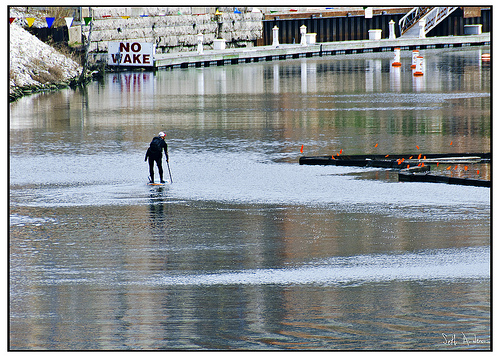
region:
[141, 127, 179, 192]
person paddle boarding on water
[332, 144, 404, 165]
small orange flags on divider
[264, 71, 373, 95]
reflection on calm water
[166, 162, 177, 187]
paddle board oar in water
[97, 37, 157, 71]
sign warning not to make wake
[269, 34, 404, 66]
dock on water's edge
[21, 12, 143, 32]
multi colored triangle flags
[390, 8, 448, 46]
ramp leading down to water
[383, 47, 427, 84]
orange and white buoys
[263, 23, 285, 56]
white post on dock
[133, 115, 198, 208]
person on floating board dressed in black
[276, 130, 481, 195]
low black partitions with orange flags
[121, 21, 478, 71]
walkway at edge of water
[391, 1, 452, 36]
ramp with railing to higher elevation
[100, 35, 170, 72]
large print on white sign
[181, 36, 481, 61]
black and white edging on side of walkway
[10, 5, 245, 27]
different colored flags hanging over water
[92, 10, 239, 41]
wall made out of thick stones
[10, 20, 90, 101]
sloped edge with green plants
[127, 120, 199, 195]
man leaning over with oar in water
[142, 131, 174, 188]
Woman standing in water.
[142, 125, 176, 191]
Woman holding a pole in the water.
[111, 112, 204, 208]
Woman carrying a backpack with stick in hand.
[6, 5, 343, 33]
Flags in many colors hanging above the water.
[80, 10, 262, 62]
Gray stone wall behind a white sign.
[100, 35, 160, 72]
No wake sign on a gray siding.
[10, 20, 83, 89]
Snow on the ground near the sign.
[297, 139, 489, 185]
Small orange flags.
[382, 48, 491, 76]
Orange and white barrels in the water.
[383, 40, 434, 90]
Six white and orange barrels in the water.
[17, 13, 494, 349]
Outdoor shot, showing natural and man-made elements.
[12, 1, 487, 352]
Daytime shot, featuring recreational pass-time.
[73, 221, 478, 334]
Clear, blue water with minimal ripples.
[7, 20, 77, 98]
Steep pile of aggregate near water's edge.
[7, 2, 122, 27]
Multicolored pennants hung on string.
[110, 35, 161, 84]
Square, 'No Wake' sign in bold letters.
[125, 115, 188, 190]
Person, wearing black, using stick to move through water on board.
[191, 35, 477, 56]
Low guardrail, abutting water.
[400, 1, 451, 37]
Metal ramp with rails.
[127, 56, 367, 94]
Reflection of white posts and sign in clear water.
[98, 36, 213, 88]
A sign saying NO WAKE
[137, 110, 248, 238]
A man on the water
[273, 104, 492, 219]
Orange flags along the border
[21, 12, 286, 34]
Different colored flags on a rope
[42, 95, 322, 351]
Calm water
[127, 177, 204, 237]
A reflection of a man standing on the water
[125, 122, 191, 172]
A person slightly bent forward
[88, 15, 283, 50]
Stone walls behind the NO WAKE sign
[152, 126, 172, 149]
A white hat on a person's head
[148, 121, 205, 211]
A man holding down a pole on the water